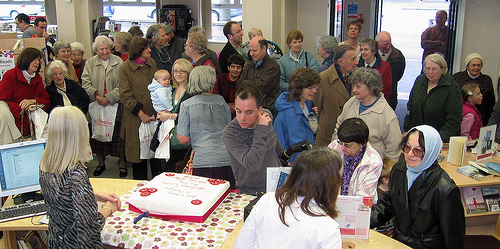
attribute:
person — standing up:
[90, 37, 127, 179]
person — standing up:
[173, 62, 232, 189]